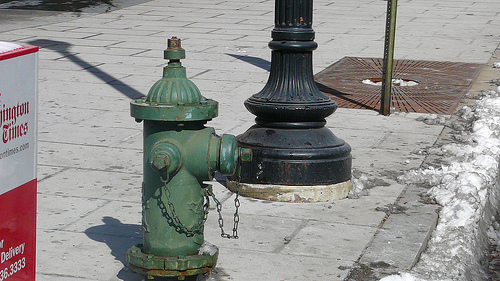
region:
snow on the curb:
[432, 160, 492, 275]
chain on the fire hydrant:
[142, 182, 258, 232]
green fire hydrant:
[137, 65, 202, 276]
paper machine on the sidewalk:
[1, 51, 49, 271]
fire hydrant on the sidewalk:
[130, 188, 252, 266]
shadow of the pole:
[30, 17, 181, 117]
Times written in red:
[8, 113, 21, 149]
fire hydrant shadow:
[66, 200, 173, 263]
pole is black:
[250, 35, 343, 170]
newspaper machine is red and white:
[6, 132, 42, 250]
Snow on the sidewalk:
[414, 88, 485, 254]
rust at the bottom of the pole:
[259, 70, 342, 199]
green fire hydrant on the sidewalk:
[130, 5, 236, 278]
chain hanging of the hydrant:
[181, 168, 263, 255]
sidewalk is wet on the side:
[370, 198, 417, 225]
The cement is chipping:
[250, 162, 348, 225]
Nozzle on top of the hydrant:
[152, 9, 184, 69]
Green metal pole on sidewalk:
[367, 4, 434, 147]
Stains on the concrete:
[55, 72, 142, 239]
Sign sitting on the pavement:
[1, 43, 75, 278]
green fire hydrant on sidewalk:
[123, 33, 258, 279]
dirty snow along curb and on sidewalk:
[353, 84, 498, 279]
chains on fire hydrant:
[158, 167, 243, 239]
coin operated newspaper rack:
[1, 39, 42, 279]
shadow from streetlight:
[26, 31, 151, 102]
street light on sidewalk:
[239, 0, 359, 201]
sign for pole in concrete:
[374, 1, 401, 116]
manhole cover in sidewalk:
[311, 55, 485, 116]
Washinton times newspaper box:
[3, 38, 40, 279]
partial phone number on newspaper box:
[1, 257, 31, 279]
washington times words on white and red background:
[3, 93, 40, 153]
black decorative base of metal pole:
[253, 61, 343, 145]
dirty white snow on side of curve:
[438, 178, 490, 257]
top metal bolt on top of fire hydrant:
[139, 24, 197, 62]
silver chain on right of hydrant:
[206, 164, 255, 245]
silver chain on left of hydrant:
[158, 179, 210, 238]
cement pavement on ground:
[278, 203, 355, 278]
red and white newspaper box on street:
[0, 38, 34, 275]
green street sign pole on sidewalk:
[381, 20, 403, 117]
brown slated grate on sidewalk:
[421, 67, 463, 122]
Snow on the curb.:
[402, 84, 498, 279]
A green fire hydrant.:
[120, 36, 250, 279]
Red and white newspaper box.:
[1, 43, 41, 278]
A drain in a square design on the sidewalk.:
[304, 50, 479, 124]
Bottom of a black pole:
[223, 0, 358, 186]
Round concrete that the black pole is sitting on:
[227, 180, 359, 205]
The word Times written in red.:
[1, 121, 31, 142]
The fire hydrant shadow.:
[29, 35, 150, 110]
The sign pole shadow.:
[230, 49, 387, 116]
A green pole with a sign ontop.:
[384, 0, 394, 116]